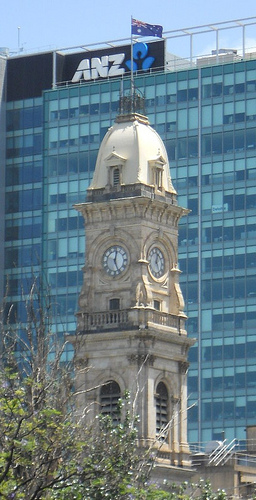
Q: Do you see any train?
A: Yes, there is a train.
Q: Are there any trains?
A: Yes, there is a train.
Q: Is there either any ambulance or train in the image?
A: Yes, there is a train.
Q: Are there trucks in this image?
A: No, there are no trucks.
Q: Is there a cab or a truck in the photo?
A: No, there are no trucks or taxis.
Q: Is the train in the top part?
A: Yes, the train is in the top of the image.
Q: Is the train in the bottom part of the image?
A: No, the train is in the top of the image.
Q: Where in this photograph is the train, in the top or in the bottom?
A: The train is in the top of the image.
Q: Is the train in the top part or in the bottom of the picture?
A: The train is in the top of the image.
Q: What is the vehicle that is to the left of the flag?
A: The vehicle is a train.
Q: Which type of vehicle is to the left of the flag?
A: The vehicle is a train.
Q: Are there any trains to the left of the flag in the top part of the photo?
A: Yes, there is a train to the left of the flag.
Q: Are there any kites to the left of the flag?
A: No, there is a train to the left of the flag.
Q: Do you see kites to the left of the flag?
A: No, there is a train to the left of the flag.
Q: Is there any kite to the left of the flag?
A: No, there is a train to the left of the flag.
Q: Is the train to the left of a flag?
A: Yes, the train is to the left of a flag.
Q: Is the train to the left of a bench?
A: No, the train is to the left of a flag.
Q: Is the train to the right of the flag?
A: No, the train is to the left of the flag.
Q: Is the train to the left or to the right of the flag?
A: The train is to the left of the flag.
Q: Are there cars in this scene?
A: No, there are no cars.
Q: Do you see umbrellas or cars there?
A: No, there are no cars or umbrellas.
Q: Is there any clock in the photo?
A: Yes, there is a clock.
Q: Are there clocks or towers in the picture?
A: Yes, there is a clock.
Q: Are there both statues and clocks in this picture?
A: No, there is a clock but no statues.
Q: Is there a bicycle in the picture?
A: No, there are no bicycles.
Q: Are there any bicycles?
A: No, there are no bicycles.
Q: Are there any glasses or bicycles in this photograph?
A: No, there are no bicycles or glasses.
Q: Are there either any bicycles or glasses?
A: No, there are no bicycles or glasses.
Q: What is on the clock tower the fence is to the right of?
A: The clock is on the clock tower.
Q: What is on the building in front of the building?
A: The clock is on the clock tower.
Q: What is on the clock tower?
A: The clock is on the clock tower.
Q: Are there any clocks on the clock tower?
A: Yes, there is a clock on the clock tower.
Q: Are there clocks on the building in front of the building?
A: Yes, there is a clock on the clock tower.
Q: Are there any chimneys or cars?
A: No, there are no cars or chimneys.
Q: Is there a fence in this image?
A: Yes, there is a fence.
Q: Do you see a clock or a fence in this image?
A: Yes, there is a fence.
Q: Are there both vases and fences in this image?
A: No, there is a fence but no vases.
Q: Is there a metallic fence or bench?
A: Yes, there is a metal fence.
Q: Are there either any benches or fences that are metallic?
A: Yes, the fence is metallic.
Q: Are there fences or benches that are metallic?
A: Yes, the fence is metallic.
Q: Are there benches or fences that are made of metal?
A: Yes, the fence is made of metal.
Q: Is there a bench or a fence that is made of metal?
A: Yes, the fence is made of metal.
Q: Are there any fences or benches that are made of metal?
A: Yes, the fence is made of metal.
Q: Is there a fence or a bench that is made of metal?
A: Yes, the fence is made of metal.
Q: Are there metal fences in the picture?
A: Yes, there is a metal fence.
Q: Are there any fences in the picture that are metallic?
A: Yes, there is a fence that is metallic.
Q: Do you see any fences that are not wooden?
A: Yes, there is a metallic fence.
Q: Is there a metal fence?
A: Yes, there is a fence that is made of metal.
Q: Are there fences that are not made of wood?
A: Yes, there is a fence that is made of metal.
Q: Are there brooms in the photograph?
A: No, there are no brooms.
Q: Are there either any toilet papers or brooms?
A: No, there are no brooms or toilet papers.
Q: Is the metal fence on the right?
A: Yes, the fence is on the right of the image.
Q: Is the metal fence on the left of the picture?
A: No, the fence is on the right of the image.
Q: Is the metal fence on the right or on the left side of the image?
A: The fence is on the right of the image.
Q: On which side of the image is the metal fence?
A: The fence is on the right of the image.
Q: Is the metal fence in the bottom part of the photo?
A: Yes, the fence is in the bottom of the image.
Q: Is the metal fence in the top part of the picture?
A: No, the fence is in the bottom of the image.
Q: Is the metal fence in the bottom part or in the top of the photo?
A: The fence is in the bottom of the image.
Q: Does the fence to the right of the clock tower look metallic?
A: Yes, the fence is metallic.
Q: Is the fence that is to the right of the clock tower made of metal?
A: Yes, the fence is made of metal.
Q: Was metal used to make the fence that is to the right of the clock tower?
A: Yes, the fence is made of metal.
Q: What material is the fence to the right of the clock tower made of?
A: The fence is made of metal.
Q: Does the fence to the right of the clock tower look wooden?
A: No, the fence is metallic.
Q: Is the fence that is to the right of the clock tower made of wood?
A: No, the fence is made of metal.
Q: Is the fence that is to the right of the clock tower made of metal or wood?
A: The fence is made of metal.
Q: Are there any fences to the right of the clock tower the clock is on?
A: Yes, there is a fence to the right of the clock tower.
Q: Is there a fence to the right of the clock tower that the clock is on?
A: Yes, there is a fence to the right of the clock tower.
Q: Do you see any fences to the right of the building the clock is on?
A: Yes, there is a fence to the right of the clock tower.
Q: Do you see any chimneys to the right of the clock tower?
A: No, there is a fence to the right of the clock tower.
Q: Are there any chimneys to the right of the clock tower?
A: No, there is a fence to the right of the clock tower.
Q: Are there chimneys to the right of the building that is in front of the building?
A: No, there is a fence to the right of the clock tower.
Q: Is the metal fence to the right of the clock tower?
A: Yes, the fence is to the right of the clock tower.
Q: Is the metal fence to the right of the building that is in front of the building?
A: Yes, the fence is to the right of the clock tower.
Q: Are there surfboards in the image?
A: No, there are no surfboards.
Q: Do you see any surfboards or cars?
A: No, there are no surfboards or cars.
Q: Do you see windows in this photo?
A: Yes, there is a window.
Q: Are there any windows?
A: Yes, there is a window.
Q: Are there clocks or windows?
A: Yes, there is a window.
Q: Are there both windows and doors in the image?
A: No, there is a window but no doors.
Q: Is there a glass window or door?
A: Yes, there is a glass window.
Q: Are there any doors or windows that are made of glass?
A: Yes, the window is made of glass.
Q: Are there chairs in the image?
A: No, there are no chairs.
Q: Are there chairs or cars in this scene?
A: No, there are no chairs or cars.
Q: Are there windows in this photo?
A: Yes, there is a window.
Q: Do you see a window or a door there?
A: Yes, there is a window.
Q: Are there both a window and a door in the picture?
A: No, there is a window but no doors.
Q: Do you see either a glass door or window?
A: Yes, there is a glass window.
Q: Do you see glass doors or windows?
A: Yes, there is a glass window.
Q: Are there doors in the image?
A: No, there are no doors.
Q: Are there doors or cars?
A: No, there are no doors or cars.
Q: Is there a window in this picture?
A: Yes, there is a window.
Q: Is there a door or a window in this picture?
A: Yes, there is a window.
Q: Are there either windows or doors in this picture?
A: Yes, there is a window.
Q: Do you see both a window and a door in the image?
A: No, there is a window but no doors.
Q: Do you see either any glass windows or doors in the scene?
A: Yes, there is a glass window.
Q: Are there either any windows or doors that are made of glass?
A: Yes, the window is made of glass.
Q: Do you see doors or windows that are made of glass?
A: Yes, the window is made of glass.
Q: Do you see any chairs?
A: No, there are no chairs.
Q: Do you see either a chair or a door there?
A: No, there are no chairs or doors.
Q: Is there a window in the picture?
A: Yes, there is a window.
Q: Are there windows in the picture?
A: Yes, there is a window.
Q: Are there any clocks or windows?
A: Yes, there is a window.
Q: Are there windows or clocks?
A: Yes, there is a window.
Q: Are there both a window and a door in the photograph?
A: No, there is a window but no doors.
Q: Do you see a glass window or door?
A: Yes, there is a glass window.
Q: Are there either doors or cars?
A: No, there are no cars or doors.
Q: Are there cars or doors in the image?
A: No, there are no cars or doors.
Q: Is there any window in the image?
A: Yes, there is a window.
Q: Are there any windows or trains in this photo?
A: Yes, there is a window.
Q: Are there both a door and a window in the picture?
A: No, there is a window but no doors.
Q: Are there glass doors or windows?
A: Yes, there is a glass window.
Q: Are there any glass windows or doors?
A: Yes, there is a glass window.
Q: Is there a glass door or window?
A: Yes, there is a glass window.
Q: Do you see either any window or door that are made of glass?
A: Yes, the window is made of glass.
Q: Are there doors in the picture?
A: No, there are no doors.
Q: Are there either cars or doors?
A: No, there are no doors or cars.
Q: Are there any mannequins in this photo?
A: No, there are no mannequins.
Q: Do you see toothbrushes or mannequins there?
A: No, there are no mannequins or toothbrushes.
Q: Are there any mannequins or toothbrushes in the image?
A: No, there are no mannequins or toothbrushes.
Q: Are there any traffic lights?
A: No, there are no traffic lights.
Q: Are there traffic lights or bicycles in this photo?
A: No, there are no traffic lights or bicycles.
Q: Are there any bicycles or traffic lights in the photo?
A: No, there are no traffic lights or bicycles.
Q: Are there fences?
A: Yes, there is a fence.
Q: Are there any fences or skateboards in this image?
A: Yes, there is a fence.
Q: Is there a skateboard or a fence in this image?
A: Yes, there is a fence.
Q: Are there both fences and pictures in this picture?
A: No, there is a fence but no pictures.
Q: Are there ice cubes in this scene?
A: No, there are no ice cubes.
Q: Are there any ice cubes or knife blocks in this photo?
A: No, there are no ice cubes or knife blocks.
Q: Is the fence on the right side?
A: Yes, the fence is on the right of the image.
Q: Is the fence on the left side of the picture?
A: No, the fence is on the right of the image.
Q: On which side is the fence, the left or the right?
A: The fence is on the right of the image.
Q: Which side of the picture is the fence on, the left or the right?
A: The fence is on the right of the image.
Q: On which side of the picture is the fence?
A: The fence is on the right of the image.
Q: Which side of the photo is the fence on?
A: The fence is on the right of the image.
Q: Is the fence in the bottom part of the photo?
A: Yes, the fence is in the bottom of the image.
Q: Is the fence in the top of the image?
A: No, the fence is in the bottom of the image.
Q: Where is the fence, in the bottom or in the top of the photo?
A: The fence is in the bottom of the image.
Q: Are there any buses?
A: No, there are no buses.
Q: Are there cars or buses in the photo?
A: No, there are no buses or cars.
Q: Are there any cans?
A: No, there are no cans.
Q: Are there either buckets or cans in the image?
A: No, there are no cans or buckets.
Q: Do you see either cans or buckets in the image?
A: No, there are no cans or buckets.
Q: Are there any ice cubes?
A: No, there are no ice cubes.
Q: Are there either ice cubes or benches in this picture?
A: No, there are no ice cubes or benches.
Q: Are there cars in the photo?
A: No, there are no cars.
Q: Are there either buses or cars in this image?
A: No, there are no cars or buses.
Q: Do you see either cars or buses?
A: No, there are no cars or buses.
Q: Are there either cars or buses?
A: No, there are no cars or buses.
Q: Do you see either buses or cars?
A: No, there are no cars or buses.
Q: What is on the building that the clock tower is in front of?
A: The sign is on the building.